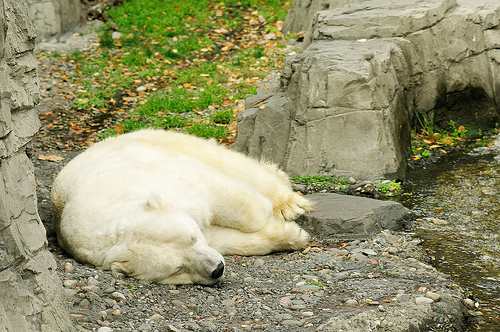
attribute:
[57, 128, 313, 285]
polar bear — white, sleeping, in captivity, sleeping on ledge, curled up, lying down, species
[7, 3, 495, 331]
ground — rocky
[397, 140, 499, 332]
stream of water — flowing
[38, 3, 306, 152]
grass — green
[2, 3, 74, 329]
cluster of stones — in background, grey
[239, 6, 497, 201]
rock emplacement — grey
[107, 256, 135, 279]
right ear — white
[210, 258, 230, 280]
nose — black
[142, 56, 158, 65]
leaf — dry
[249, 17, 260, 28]
leaf — brown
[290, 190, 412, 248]
rock — flat, muddy, grey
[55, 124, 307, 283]
fur — white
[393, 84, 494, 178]
crevice — black